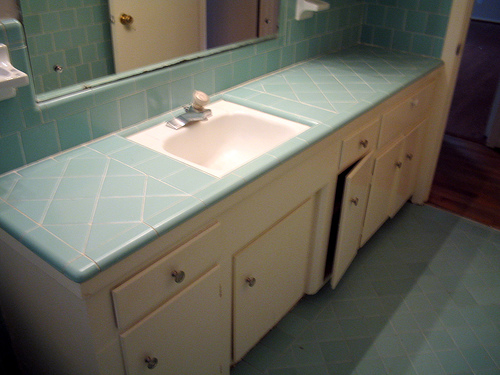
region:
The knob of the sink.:
[195, 88, 205, 105]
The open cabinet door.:
[320, 149, 364, 293]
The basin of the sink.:
[162, 109, 290, 174]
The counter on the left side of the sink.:
[6, 129, 221, 277]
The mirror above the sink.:
[20, 9, 258, 101]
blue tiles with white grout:
[2, 0, 439, 272]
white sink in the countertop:
[138, 82, 295, 173]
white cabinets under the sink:
[7, 78, 445, 373]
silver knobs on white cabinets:
[149, 102, 426, 372]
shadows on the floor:
[241, 209, 483, 373]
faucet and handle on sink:
[165, 89, 212, 124]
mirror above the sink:
[20, 2, 272, 94]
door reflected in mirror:
[105, 1, 207, 70]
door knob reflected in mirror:
[120, 13, 134, 28]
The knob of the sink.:
[189, 90, 211, 107]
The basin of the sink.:
[170, 116, 284, 176]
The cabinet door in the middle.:
[232, 189, 327, 344]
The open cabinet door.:
[312, 163, 382, 288]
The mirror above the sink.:
[20, 5, 284, 95]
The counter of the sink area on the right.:
[246, 39, 413, 131]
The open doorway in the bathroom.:
[427, 2, 498, 227]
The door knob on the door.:
[122, 16, 136, 28]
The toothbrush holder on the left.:
[0, 49, 31, 97]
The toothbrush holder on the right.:
[295, 0, 329, 24]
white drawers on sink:
[123, 228, 243, 373]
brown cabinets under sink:
[138, 278, 345, 363]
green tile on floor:
[336, 277, 471, 357]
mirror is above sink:
[11, 9, 303, 95]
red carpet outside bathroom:
[451, 123, 496, 225]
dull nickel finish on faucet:
[161, 89, 228, 144]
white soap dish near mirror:
[1, 49, 33, 105]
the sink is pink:
[165, 118, 289, 163]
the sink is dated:
[152, 111, 289, 166]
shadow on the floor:
[361, 215, 438, 370]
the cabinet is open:
[332, 158, 367, 316]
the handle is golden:
[120, 15, 135, 34]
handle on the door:
[110, 5, 189, 60]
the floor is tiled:
[340, 240, 492, 372]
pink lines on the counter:
[42, 166, 152, 253]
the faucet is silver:
[178, 103, 215, 124]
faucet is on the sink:
[161, 94, 270, 159]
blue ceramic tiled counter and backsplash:
[3, 0, 456, 272]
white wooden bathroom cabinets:
[14, 75, 476, 360]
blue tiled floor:
[254, 210, 493, 373]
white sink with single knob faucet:
[122, 88, 311, 177]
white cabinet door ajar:
[322, 149, 371, 291]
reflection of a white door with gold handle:
[107, 0, 199, 74]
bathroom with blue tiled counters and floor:
[0, 0, 498, 373]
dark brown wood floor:
[420, 129, 499, 232]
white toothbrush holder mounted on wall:
[0, 42, 30, 102]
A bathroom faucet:
[159, 84, 221, 139]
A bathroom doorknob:
[117, 10, 140, 33]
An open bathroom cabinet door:
[326, 144, 381, 292]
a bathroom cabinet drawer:
[101, 217, 229, 332]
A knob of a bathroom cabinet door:
[239, 269, 259, 294]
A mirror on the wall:
[27, 0, 305, 50]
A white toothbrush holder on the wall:
[2, 36, 29, 105]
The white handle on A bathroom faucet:
[189, 84, 210, 110]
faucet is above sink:
[166, 89, 213, 129]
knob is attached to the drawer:
[168, 269, 185, 282]